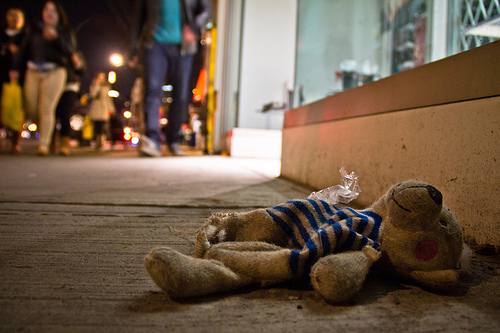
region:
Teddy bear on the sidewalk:
[123, 156, 485, 314]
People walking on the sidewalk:
[5, 0, 210, 188]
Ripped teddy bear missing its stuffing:
[122, 160, 483, 315]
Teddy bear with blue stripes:
[136, 165, 484, 298]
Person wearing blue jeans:
[81, 1, 213, 170]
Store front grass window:
[275, 0, 495, 110]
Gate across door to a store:
[427, 0, 497, 60]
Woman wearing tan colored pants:
[8, 0, 78, 165]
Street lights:
[101, 42, 138, 141]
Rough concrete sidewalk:
[18, 152, 129, 314]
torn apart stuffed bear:
[143, 161, 481, 300]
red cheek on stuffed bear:
[393, 225, 458, 291]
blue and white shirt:
[273, 170, 397, 295]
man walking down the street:
[121, 7, 216, 175]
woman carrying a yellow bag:
[7, 6, 84, 178]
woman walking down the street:
[7, 2, 87, 166]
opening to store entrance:
[226, 2, 317, 187]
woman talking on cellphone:
[86, 61, 123, 150]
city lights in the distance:
[97, 41, 146, 161]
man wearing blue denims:
[113, 36, 199, 175]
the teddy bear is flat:
[141, 147, 476, 314]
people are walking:
[0, 0, 267, 197]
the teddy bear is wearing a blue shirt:
[136, 148, 471, 325]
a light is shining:
[91, 35, 148, 97]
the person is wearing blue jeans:
[118, 3, 243, 195]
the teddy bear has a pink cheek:
[354, 165, 487, 305]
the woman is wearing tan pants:
[9, 3, 101, 166]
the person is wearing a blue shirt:
[115, 0, 239, 182]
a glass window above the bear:
[131, 0, 494, 329]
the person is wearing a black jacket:
[96, 0, 221, 165]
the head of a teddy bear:
[372, 173, 492, 297]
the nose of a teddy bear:
[421, 178, 446, 205]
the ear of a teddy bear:
[409, 261, 465, 290]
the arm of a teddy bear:
[299, 245, 391, 303]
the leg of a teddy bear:
[140, 241, 244, 303]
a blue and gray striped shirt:
[260, 190, 393, 285]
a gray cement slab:
[4, 195, 498, 332]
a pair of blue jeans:
[139, 37, 206, 144]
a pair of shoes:
[136, 135, 196, 162]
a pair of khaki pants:
[19, 62, 79, 150]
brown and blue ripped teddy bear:
[176, 176, 450, 296]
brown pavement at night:
[23, 179, 131, 314]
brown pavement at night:
[23, 153, 264, 200]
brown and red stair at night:
[298, 111, 493, 167]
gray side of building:
[243, 9, 273, 97]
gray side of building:
[306, 7, 366, 52]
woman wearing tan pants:
[22, 63, 62, 148]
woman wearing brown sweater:
[25, 30, 65, 60]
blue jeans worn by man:
[137, 38, 192, 138]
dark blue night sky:
[82, 10, 147, 42]